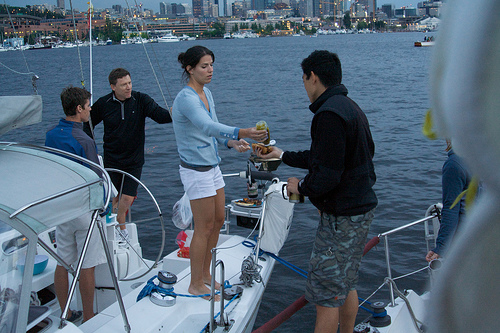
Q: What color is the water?
A: Blue.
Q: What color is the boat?
A: White.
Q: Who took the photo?
A: Someone on the boat.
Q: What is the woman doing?
A: Putting something on the man's hotdog.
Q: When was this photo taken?
A: During the day.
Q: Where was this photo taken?
A: On the water.